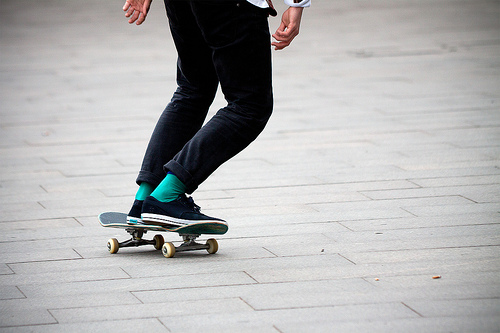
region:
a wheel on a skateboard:
[160, 239, 177, 259]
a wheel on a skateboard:
[203, 234, 220, 259]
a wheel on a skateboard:
[103, 235, 120, 257]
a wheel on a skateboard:
[151, 232, 166, 250]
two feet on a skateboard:
[98, 196, 234, 233]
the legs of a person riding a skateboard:
[123, 0, 281, 225]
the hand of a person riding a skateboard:
[272, 4, 305, 53]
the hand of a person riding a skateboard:
[118, 0, 152, 27]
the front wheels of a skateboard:
[158, 233, 223, 263]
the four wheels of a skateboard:
[104, 228, 221, 262]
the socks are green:
[134, 175, 189, 205]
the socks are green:
[121, 169, 202, 215]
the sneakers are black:
[119, 184, 216, 236]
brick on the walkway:
[254, 258, 349, 280]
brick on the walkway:
[254, 288, 372, 305]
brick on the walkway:
[151, 298, 230, 314]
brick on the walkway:
[68, 289, 137, 316]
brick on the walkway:
[361, 206, 424, 231]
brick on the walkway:
[9, 218, 74, 235]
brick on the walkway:
[42, 183, 102, 212]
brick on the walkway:
[384, 200, 433, 214]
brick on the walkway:
[298, 178, 350, 200]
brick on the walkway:
[389, 293, 462, 318]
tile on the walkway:
[261, 256, 354, 273]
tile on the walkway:
[251, 283, 375, 305]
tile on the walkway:
[362, 204, 416, 226]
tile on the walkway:
[36, 286, 129, 303]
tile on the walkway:
[46, 179, 87, 206]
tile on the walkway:
[357, 185, 420, 198]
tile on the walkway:
[297, 176, 363, 190]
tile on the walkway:
[346, 141, 397, 160]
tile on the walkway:
[299, 235, 364, 256]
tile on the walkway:
[318, 142, 375, 169]